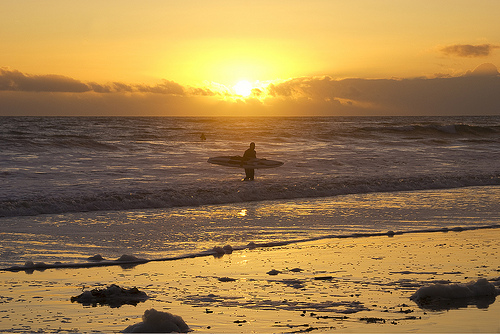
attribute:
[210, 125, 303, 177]
surf boarder — walking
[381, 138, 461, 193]
water — blue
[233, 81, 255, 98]
sun — ball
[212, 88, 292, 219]
man — walking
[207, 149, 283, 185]
surfboard — distance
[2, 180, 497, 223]
ripples — blue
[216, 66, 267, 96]
sun — setting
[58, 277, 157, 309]
rock — jagged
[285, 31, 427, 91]
sky — clear, orange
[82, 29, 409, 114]
sky — orange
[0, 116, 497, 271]
water — blue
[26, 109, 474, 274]
water — blue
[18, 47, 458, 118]
sun — setting